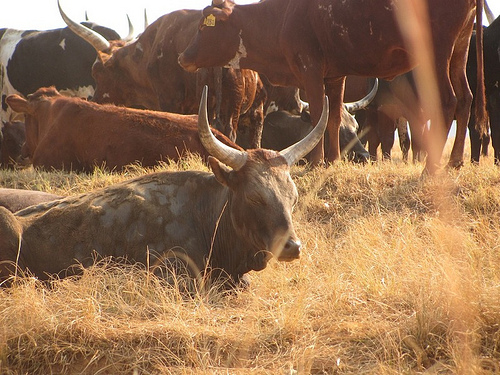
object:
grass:
[0, 139, 500, 375]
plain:
[0, 136, 500, 375]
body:
[53, 96, 223, 164]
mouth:
[275, 245, 300, 262]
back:
[263, 0, 385, 9]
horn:
[55, 0, 110, 53]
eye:
[200, 24, 206, 29]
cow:
[178, 0, 490, 170]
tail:
[473, 0, 490, 139]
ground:
[0, 225, 499, 375]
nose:
[177, 53, 184, 66]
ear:
[202, 0, 231, 20]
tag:
[204, 14, 215, 27]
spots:
[326, 10, 336, 19]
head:
[177, 0, 245, 73]